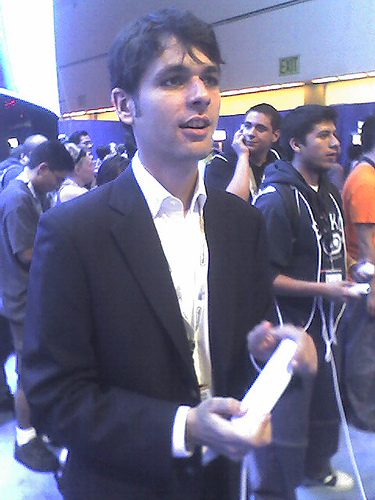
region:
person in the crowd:
[106, 39, 220, 313]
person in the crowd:
[351, 115, 374, 182]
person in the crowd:
[8, 147, 70, 212]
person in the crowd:
[70, 149, 95, 189]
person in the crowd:
[95, 142, 128, 173]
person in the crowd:
[75, 131, 93, 154]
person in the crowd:
[115, 138, 123, 154]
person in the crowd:
[73, 129, 96, 150]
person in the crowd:
[29, 131, 42, 152]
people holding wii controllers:
[211, 251, 374, 448]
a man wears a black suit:
[19, 164, 279, 498]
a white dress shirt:
[128, 151, 205, 381]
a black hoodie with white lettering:
[255, 162, 348, 328]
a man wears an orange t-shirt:
[341, 116, 374, 281]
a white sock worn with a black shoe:
[12, 425, 60, 474]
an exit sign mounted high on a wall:
[278, 53, 302, 79]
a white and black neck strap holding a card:
[173, 224, 213, 405]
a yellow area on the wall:
[66, 73, 374, 121]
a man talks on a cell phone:
[229, 99, 282, 162]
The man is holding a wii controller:
[230, 338, 298, 433]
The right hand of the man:
[188, 398, 272, 460]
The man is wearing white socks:
[13, 427, 36, 445]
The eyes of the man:
[162, 74, 218, 88]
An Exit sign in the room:
[279, 56, 298, 75]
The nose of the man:
[189, 78, 209, 105]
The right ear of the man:
[107, 87, 133, 122]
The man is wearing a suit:
[19, 152, 283, 499]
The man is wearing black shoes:
[14, 440, 57, 474]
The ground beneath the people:
[0, 409, 373, 499]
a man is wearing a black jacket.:
[81, 276, 146, 338]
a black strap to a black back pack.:
[276, 183, 299, 218]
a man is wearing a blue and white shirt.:
[327, 212, 340, 239]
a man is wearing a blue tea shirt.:
[9, 196, 26, 236]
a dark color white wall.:
[319, 20, 367, 58]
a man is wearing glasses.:
[50, 169, 70, 188]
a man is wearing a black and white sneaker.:
[300, 461, 357, 494]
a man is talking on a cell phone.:
[229, 102, 284, 160]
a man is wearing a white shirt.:
[174, 225, 200, 277]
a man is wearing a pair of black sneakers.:
[9, 435, 59, 474]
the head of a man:
[82, 29, 248, 165]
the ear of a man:
[100, 73, 153, 139]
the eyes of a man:
[146, 52, 246, 99]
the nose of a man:
[168, 63, 234, 132]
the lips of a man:
[162, 97, 233, 153]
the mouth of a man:
[167, 86, 249, 152]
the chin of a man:
[159, 129, 249, 175]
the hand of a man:
[175, 372, 316, 466]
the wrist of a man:
[139, 357, 248, 468]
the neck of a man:
[83, 125, 223, 268]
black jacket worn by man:
[34, 183, 313, 494]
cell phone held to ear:
[231, 95, 281, 170]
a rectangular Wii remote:
[230, 337, 299, 436]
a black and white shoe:
[306, 469, 354, 491]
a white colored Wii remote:
[344, 282, 371, 295]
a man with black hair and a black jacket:
[250, 104, 373, 499]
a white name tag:
[199, 382, 210, 400]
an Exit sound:
[276, 55, 299, 77]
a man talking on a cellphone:
[205, 101, 288, 199]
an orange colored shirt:
[340, 158, 373, 271]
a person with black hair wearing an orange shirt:
[339, 113, 373, 434]